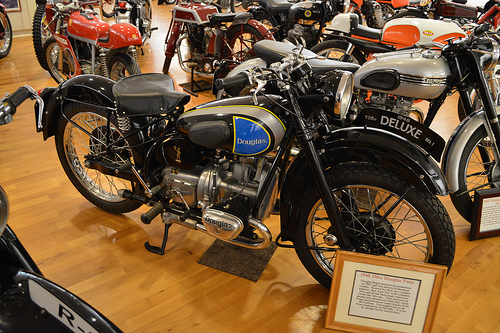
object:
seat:
[107, 70, 190, 112]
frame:
[322, 247, 447, 332]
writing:
[351, 272, 421, 316]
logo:
[232, 117, 274, 159]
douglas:
[235, 134, 270, 145]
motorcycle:
[38, 0, 150, 87]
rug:
[196, 237, 281, 282]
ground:
[0, 0, 500, 331]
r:
[54, 301, 77, 327]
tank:
[157, 165, 200, 210]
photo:
[322, 247, 453, 331]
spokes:
[70, 116, 92, 159]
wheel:
[49, 99, 152, 215]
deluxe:
[379, 113, 423, 140]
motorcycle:
[208, 22, 500, 224]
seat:
[253, 38, 364, 75]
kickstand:
[144, 218, 182, 255]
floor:
[0, 0, 499, 332]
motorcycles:
[32, 45, 459, 298]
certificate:
[467, 185, 499, 241]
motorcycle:
[157, 0, 278, 79]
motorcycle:
[308, 6, 500, 123]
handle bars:
[211, 69, 272, 92]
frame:
[465, 186, 499, 241]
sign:
[358, 108, 446, 163]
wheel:
[291, 160, 456, 292]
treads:
[140, 203, 165, 225]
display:
[0, 0, 498, 332]